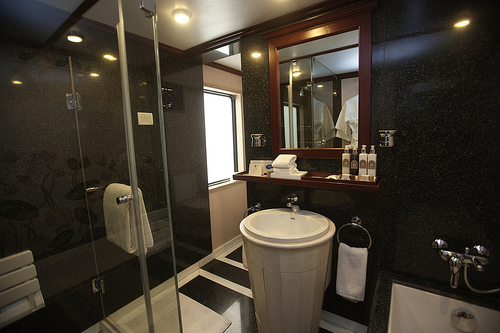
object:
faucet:
[283, 192, 302, 211]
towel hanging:
[113, 195, 132, 203]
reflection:
[308, 97, 336, 148]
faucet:
[432, 238, 490, 289]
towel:
[101, 182, 156, 257]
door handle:
[116, 193, 132, 205]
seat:
[0, 248, 46, 321]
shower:
[0, 0, 183, 332]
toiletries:
[366, 145, 376, 182]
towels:
[270, 153, 297, 169]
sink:
[242, 209, 332, 244]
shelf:
[230, 169, 384, 192]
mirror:
[276, 29, 360, 149]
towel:
[334, 242, 371, 301]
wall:
[240, 2, 500, 302]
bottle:
[340, 144, 350, 181]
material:
[19, 106, 39, 135]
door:
[0, 0, 182, 332]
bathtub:
[369, 267, 497, 331]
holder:
[336, 216, 373, 251]